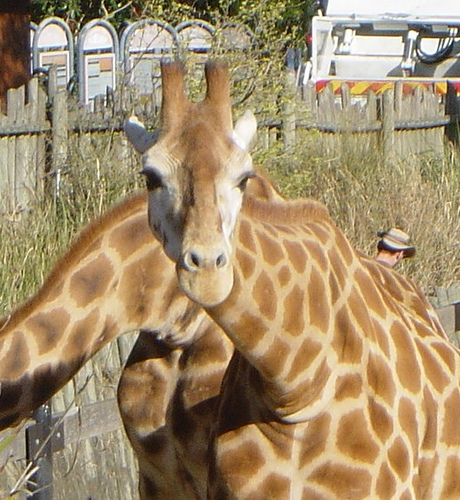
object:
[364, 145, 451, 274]
weeds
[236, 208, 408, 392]
neck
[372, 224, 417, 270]
man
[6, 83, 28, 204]
wooden posts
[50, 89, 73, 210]
post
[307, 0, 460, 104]
truck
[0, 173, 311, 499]
giraffe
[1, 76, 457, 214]
fence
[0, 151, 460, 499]
ground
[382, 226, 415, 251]
hat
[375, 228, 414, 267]
head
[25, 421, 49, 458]
hinge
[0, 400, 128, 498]
door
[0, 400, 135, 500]
fence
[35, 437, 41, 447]
screws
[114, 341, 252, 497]
abdomen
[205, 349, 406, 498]
abdomen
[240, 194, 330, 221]
bristles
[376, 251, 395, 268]
neck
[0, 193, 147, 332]
bristles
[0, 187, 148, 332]
neck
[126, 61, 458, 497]
giraffe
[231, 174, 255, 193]
eye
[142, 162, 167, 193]
eye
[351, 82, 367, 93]
yellow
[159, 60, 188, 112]
horn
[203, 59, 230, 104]
horn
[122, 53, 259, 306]
head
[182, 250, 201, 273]
nostrils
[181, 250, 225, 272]
nose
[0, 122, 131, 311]
grass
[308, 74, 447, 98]
stripe